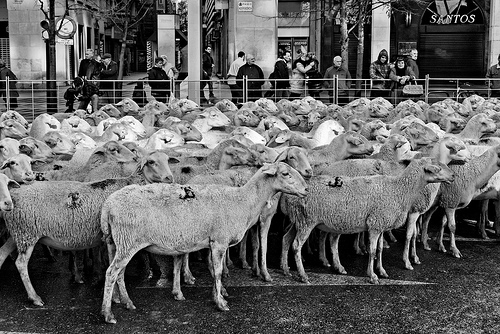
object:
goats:
[97, 161, 309, 324]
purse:
[403, 79, 424, 95]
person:
[387, 57, 416, 85]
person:
[405, 47, 418, 85]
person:
[147, 57, 171, 102]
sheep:
[274, 157, 455, 285]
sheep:
[142, 127, 186, 148]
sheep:
[302, 110, 323, 129]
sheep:
[192, 106, 232, 131]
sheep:
[305, 130, 375, 163]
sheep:
[166, 137, 262, 184]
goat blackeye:
[281, 172, 290, 176]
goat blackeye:
[148, 158, 155, 165]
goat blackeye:
[9, 161, 17, 168]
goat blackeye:
[289, 156, 296, 159]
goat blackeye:
[45, 140, 55, 145]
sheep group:
[0, 97, 500, 324]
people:
[63, 76, 103, 115]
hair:
[132, 150, 175, 183]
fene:
[0, 72, 500, 115]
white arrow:
[136, 262, 439, 288]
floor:
[0, 238, 500, 334]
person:
[368, 49, 392, 102]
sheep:
[148, 122, 203, 143]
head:
[0, 153, 44, 183]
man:
[234, 53, 265, 109]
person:
[154, 54, 179, 94]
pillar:
[187, 0, 203, 107]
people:
[226, 50, 246, 108]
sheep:
[46, 138, 137, 181]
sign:
[412, 0, 493, 26]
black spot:
[90, 177, 120, 191]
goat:
[0, 151, 172, 307]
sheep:
[437, 147, 500, 258]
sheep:
[180, 144, 315, 286]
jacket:
[235, 61, 264, 98]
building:
[0, 0, 500, 106]